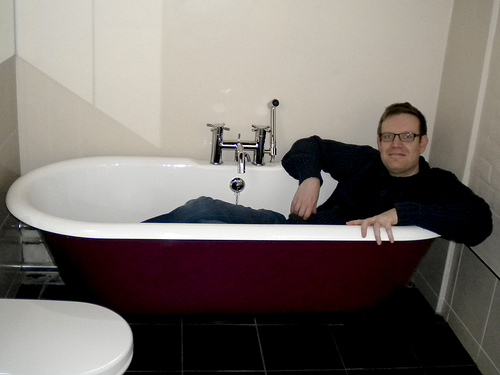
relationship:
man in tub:
[345, 106, 451, 218] [56, 161, 152, 258]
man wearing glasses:
[345, 106, 451, 218] [384, 129, 429, 148]